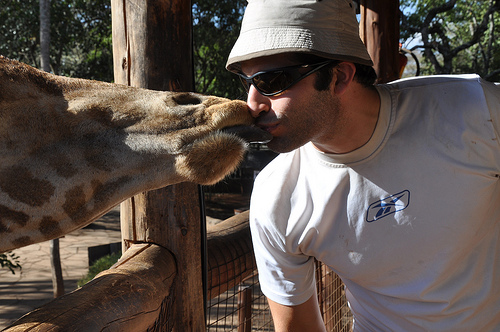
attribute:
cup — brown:
[11, 52, 248, 259]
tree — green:
[389, 5, 499, 72]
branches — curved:
[421, 19, 443, 68]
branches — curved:
[452, 19, 499, 51]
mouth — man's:
[258, 119, 280, 132]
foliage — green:
[165, 16, 252, 119]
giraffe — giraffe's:
[16, 70, 266, 220]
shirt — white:
[244, 77, 496, 327]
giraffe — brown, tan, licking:
[0, 53, 251, 255]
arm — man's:
[252, 172, 329, 329]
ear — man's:
[328, 60, 358, 100]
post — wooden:
[106, 2, 216, 330]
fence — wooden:
[115, 208, 355, 325]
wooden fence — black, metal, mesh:
[190, 227, 289, 322]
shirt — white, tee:
[481, 70, 499, 330]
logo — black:
[359, 185, 414, 225]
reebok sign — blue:
[362, 190, 420, 221]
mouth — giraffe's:
[175, 98, 272, 176]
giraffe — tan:
[3, 57, 271, 250]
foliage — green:
[6, 3, 492, 181]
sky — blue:
[0, 1, 499, 78]